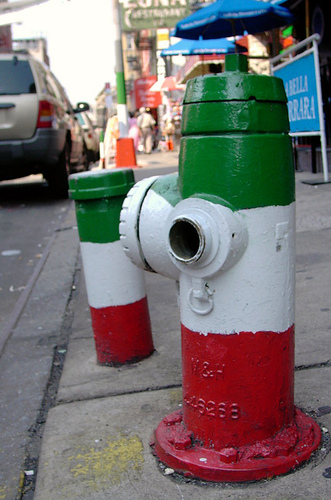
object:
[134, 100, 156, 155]
person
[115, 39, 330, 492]
hydrant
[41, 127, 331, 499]
sidewalk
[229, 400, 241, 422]
number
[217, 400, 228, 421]
6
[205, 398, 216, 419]
2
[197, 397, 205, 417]
6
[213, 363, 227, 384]
h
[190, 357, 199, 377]
h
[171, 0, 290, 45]
umbrella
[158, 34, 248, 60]
umbrella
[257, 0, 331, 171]
building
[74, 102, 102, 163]
car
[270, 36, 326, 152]
sign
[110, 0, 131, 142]
light pole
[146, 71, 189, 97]
umbrella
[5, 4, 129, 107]
sky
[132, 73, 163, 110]
sign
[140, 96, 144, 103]
letters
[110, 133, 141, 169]
block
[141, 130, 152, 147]
khaki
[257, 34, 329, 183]
frame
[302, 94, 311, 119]
lettering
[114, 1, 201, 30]
sign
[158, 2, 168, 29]
letters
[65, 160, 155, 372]
pole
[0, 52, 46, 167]
back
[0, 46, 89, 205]
vehicle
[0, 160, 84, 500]
road